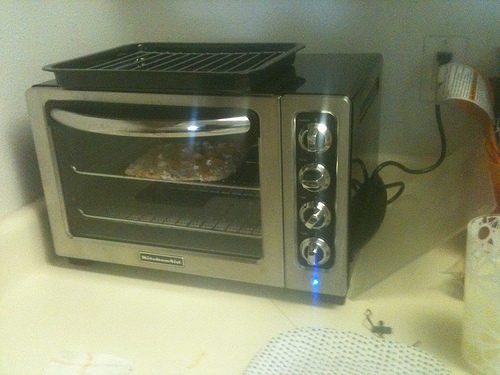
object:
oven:
[28, 48, 390, 313]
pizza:
[120, 136, 250, 188]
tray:
[42, 33, 309, 94]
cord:
[371, 69, 451, 208]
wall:
[303, 1, 377, 41]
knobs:
[296, 233, 333, 268]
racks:
[68, 181, 268, 239]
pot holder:
[235, 322, 450, 374]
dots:
[331, 350, 356, 360]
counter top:
[1, 157, 499, 375]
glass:
[463, 212, 499, 369]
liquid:
[479, 339, 493, 346]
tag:
[435, 60, 497, 126]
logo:
[137, 253, 187, 267]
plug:
[433, 50, 456, 64]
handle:
[49, 104, 252, 146]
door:
[18, 85, 284, 292]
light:
[309, 278, 326, 292]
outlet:
[418, 30, 471, 104]